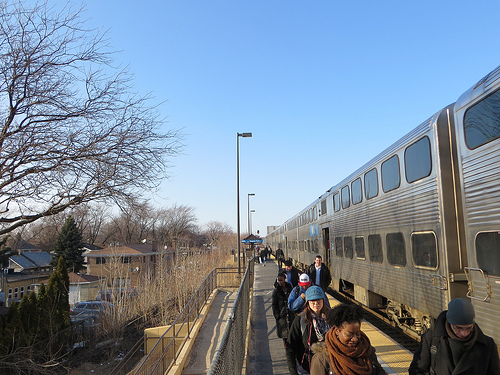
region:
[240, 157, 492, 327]
the train is at the station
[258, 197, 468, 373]
the people are walking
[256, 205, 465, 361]
the people got off the train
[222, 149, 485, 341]
the train has passengers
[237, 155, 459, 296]
the train is silver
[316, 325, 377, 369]
woman is wearing a scarf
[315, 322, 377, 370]
the scarf is brown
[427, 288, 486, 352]
person is wearing a hat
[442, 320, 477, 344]
person is wearing glasses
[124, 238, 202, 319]
the trees are bare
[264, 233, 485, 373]
a line of people next to a train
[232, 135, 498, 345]
a silver train with many cars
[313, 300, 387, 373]
a woman wearing a brown scarf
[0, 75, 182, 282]
a bare tree to the right of the people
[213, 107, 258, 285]
a light post to the right of the train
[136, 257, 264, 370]
a concrete walking path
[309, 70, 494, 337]
square windows on a train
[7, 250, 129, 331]
cars next to a building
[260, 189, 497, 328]
a blue sign on the train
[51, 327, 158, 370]
litter on the ground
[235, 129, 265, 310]
large gray lampposts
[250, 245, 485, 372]
a bunch of people next to train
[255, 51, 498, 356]
large metal train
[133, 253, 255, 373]
gray metal fence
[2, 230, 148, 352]
two houses in the left side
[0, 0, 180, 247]
brown wooden branches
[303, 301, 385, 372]
woman with brown scarf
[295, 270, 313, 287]
red and white cap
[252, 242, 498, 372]
people walking on sidewalk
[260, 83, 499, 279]
a bunch of windowson train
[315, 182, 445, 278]
silver car on passenger train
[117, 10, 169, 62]
whiet clouds in blue sky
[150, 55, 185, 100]
whiet clouds in blue sky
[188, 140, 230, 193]
whiet clouds in blue sky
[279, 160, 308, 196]
whiet clouds in blue sky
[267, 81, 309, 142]
whiet clouds in blue sky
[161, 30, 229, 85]
whiet clouds in blue sky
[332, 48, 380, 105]
whiet clouds in blue sky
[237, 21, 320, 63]
whiet clouds in blue sky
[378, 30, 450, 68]
whiet clouds in blue sky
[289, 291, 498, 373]
People in the foreground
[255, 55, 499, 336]
A side view of a train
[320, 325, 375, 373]
Woman is wearing a brown scarf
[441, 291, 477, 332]
Person is wearing a knit cap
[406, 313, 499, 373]
Person is wearing a dark colored coat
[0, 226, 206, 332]
Houses are in the background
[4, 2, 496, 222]
The sky is clear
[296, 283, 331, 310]
Woman is wearing a blue cap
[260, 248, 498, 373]
People are walking forward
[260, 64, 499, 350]
The train is silver in color